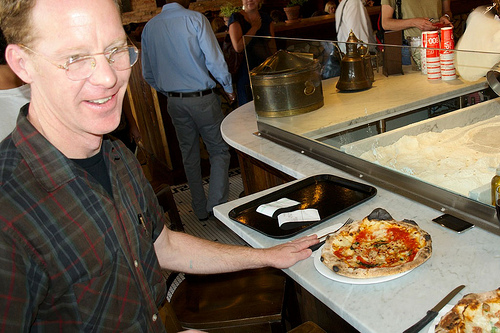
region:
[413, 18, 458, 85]
three stacks of paper cups on counter top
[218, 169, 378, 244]
black food tray on counter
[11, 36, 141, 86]
pair of glasses on face of man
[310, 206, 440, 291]
pizza on white plate on counter top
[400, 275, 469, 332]
knife on counter top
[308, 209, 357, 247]
fork on counter top next to pizza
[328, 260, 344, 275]
burn mark on pizza crust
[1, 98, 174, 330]
brown, blue and red plaid shirt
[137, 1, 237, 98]
blue long sleeve shirt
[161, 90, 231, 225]
pair of grey pants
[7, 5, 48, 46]
man has light brown hair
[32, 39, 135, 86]
man is wearing glasses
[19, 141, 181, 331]
man has blue and red shirt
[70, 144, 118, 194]
man has black shirt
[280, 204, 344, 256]
man has hand on fork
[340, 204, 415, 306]
pizza on white plate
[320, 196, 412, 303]
white plate is circular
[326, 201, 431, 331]
plate on grey counter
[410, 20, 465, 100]
red and white soda cups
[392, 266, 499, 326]
knife next to pizza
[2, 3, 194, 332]
Man is wearing glasses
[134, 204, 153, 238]
pen in pocket of shirt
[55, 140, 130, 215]
t-shirt is black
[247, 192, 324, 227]
receipts on black tray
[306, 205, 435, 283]
pizza on white plate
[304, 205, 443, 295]
pizza on counter top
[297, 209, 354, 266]
napkin on counter top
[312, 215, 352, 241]
fork on napkin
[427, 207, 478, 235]
black cell phone on counter top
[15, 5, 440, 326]
a man is going to eat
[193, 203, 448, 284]
the man is going to eat pizza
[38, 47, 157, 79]
the man is wearing glasses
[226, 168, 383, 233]
a tray sits on the counter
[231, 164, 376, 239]
the tray is black in color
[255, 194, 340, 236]
the tray has two receipts on it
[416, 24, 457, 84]
some drinking cups are stacked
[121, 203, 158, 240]
the man has a pen in his pocket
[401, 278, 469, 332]
a knife sits on the counter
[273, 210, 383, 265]
the man rests his hand on the fork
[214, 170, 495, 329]
gray counter area with a black tray and food plates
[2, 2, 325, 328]
man with plaid shirt wearing glasses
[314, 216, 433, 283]
small single serve pizza on a white plate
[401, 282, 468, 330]
knife laying on a gray counter next to pizza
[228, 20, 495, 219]
service area in a cafeteria with steam table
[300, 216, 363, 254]
white napkin with a fork and knife on it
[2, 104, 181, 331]
black undershirt under a dark plaid shirt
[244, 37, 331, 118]
black and brass metal tin with a lid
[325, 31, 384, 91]
black and brass covered pitcher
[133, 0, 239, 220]
man wearing gray slacks and blue shirt